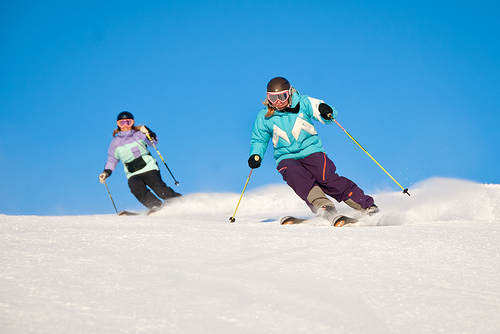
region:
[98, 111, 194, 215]
skier wearing a black helmet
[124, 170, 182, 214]
skier wearing black snow pants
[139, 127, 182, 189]
skier holding ski pole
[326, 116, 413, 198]
ski pole is yellow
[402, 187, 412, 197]
black tip of ski pole is pointy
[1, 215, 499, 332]
snow is white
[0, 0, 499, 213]
sky is blue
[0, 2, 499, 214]
sky is clear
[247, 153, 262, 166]
skier wearing black gloves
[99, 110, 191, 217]
skier to the left of skier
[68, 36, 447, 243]
Two skiers going down hill.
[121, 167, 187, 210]
Pair of black ski pants.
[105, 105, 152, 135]
Black helmet and pink goggles.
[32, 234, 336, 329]
Well groomed snow on ski run.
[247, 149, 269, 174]
Black ski glove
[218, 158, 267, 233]
Yellow ski pole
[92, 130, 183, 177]
Purple and blue ski jacket.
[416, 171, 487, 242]
snow blown up from skis.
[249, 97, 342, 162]
Blue and white ski jacket.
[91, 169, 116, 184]
White ski glove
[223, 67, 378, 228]
this is a man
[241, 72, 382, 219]
the man is snow skating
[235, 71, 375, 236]
the man is slanting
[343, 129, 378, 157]
this is a stick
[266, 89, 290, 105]
he is wearing goggles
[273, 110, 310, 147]
the jacket is heavy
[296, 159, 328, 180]
the trousers are purple in color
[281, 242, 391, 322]
the place is full of snow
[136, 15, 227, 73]
the sky is clear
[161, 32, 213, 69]
the sky is blue in color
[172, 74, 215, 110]
clear blue sky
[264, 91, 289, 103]
the big pink goggles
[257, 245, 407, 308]
the white snow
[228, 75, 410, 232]
skiier on the right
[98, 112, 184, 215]
skiier on the left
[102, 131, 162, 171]
purple and blue winter jacket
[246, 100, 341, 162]
blue and white winter jacket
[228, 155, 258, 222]
ski pole in right hand of woman on the right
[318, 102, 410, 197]
ski pole in left hand of skiier on right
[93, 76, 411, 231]
two skiiers going down the hill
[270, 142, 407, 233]
person skiing in purple pants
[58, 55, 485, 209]
two people skiing together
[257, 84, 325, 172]
person in blue and white jacket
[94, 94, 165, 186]
person in purple and blue jacket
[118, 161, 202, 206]
person wearing black ski pants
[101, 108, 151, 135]
person wearing pink goggles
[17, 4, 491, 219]
blue skies in photograph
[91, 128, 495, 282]
people skiing causes blowing snow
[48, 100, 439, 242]
four ski poles in photo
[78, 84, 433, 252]
two people skiing downhill